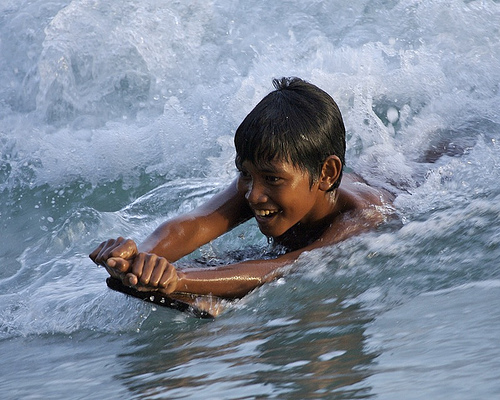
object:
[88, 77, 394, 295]
boy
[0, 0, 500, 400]
ocean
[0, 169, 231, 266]
wave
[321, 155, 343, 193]
ear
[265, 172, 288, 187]
eyes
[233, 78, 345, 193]
hair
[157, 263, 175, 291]
fingers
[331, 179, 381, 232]
skin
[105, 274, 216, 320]
surfboard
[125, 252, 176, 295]
fists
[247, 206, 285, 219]
mouth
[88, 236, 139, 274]
hands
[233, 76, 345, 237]
head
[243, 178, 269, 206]
nose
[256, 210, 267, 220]
teeth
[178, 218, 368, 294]
arms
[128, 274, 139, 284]
thumbnail